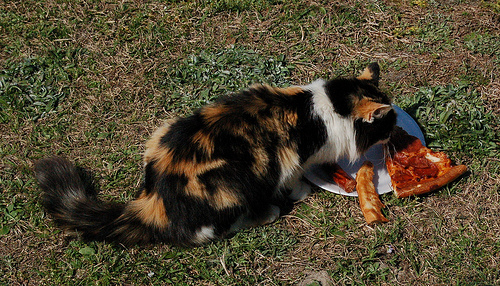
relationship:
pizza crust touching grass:
[354, 158, 387, 227] [1, 0, 498, 284]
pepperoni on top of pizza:
[390, 170, 414, 186] [384, 126, 463, 202]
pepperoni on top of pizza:
[409, 154, 439, 180] [384, 126, 463, 202]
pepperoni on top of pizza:
[395, 131, 422, 155] [384, 126, 463, 202]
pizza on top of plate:
[384, 126, 463, 202] [302, 106, 426, 198]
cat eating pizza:
[33, 55, 397, 248] [384, 126, 463, 202]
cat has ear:
[33, 55, 397, 248] [356, 96, 392, 124]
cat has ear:
[33, 55, 397, 248] [356, 61, 381, 87]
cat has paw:
[33, 55, 397, 248] [284, 176, 312, 206]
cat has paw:
[33, 55, 397, 248] [243, 201, 282, 229]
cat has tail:
[33, 55, 397, 248] [29, 153, 166, 243]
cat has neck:
[33, 55, 397, 248] [304, 77, 357, 176]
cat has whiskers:
[33, 55, 397, 248] [373, 137, 400, 172]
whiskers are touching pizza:
[373, 137, 400, 172] [384, 126, 463, 202]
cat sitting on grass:
[33, 55, 397, 248] [1, 0, 498, 284]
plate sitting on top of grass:
[302, 106, 426, 198] [1, 0, 498, 284]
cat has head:
[33, 55, 397, 248] [310, 59, 398, 162]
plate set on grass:
[302, 106, 426, 198] [1, 0, 498, 284]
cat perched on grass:
[33, 55, 397, 248] [1, 0, 498, 284]